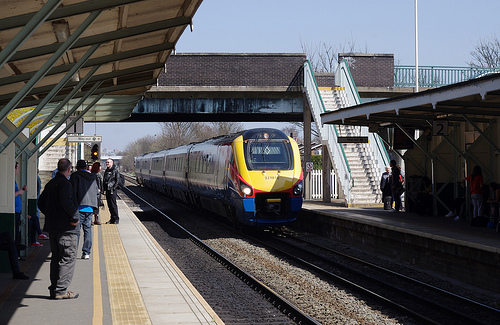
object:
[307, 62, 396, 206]
flight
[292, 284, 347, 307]
gravel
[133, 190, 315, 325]
tracks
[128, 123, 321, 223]
train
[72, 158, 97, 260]
person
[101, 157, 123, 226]
person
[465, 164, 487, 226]
person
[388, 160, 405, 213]
person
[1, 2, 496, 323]
station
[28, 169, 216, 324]
platform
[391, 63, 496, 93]
guardrail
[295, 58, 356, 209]
wall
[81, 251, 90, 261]
sneakers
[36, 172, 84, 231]
jacket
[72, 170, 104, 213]
jacket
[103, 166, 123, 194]
jacket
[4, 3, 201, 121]
roof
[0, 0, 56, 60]
beams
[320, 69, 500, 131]
roof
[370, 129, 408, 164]
beams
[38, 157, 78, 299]
people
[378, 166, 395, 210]
people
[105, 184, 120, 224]
pants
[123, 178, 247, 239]
shadow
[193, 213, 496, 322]
ground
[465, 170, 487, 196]
shirt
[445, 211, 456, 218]
shoes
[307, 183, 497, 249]
platform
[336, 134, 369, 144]
sign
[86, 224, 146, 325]
line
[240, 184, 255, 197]
headlight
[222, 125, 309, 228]
front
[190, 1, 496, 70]
sky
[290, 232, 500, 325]
track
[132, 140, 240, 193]
side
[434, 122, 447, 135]
2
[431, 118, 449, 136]
sign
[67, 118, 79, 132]
1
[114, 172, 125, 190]
backpack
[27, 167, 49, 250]
person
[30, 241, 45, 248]
shoes